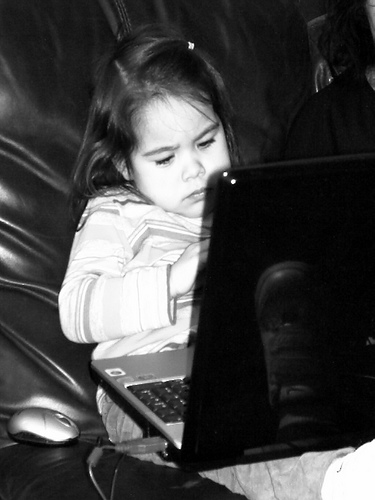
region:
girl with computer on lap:
[43, 40, 368, 487]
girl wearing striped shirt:
[45, 171, 303, 353]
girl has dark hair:
[66, 28, 263, 210]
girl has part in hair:
[83, 45, 162, 109]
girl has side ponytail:
[132, 32, 241, 100]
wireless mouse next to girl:
[0, 386, 100, 489]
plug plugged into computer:
[70, 416, 181, 499]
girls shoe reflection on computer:
[235, 238, 357, 457]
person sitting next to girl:
[264, 0, 371, 203]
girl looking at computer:
[87, 69, 302, 282]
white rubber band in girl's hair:
[187, 39, 195, 50]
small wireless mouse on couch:
[5, 405, 81, 445]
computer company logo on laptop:
[105, 365, 126, 378]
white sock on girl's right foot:
[320, 427, 373, 498]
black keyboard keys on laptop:
[121, 374, 184, 425]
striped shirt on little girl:
[53, 187, 195, 377]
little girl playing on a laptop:
[43, 28, 234, 358]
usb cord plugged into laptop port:
[85, 431, 169, 499]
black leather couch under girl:
[1, 1, 257, 498]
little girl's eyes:
[131, 118, 225, 174]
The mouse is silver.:
[6, 405, 79, 449]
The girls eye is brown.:
[151, 152, 177, 164]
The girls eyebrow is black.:
[143, 143, 179, 164]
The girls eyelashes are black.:
[143, 145, 178, 165]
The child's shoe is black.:
[253, 263, 325, 404]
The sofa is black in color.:
[13, 232, 52, 297]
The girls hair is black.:
[71, 22, 235, 215]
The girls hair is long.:
[74, 21, 244, 237]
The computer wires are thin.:
[84, 437, 123, 499]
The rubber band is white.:
[185, 40, 196, 49]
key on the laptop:
[167, 414, 180, 424]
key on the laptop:
[158, 407, 168, 414]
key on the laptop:
[147, 397, 157, 401]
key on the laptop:
[138, 391, 150, 399]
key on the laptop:
[130, 382, 154, 387]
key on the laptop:
[159, 385, 170, 394]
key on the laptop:
[167, 393, 177, 399]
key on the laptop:
[172, 397, 182, 406]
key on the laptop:
[175, 403, 183, 411]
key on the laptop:
[173, 378, 181, 384]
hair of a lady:
[165, 15, 201, 51]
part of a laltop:
[208, 409, 232, 443]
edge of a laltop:
[183, 377, 196, 402]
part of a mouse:
[32, 404, 70, 453]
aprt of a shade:
[281, 396, 301, 426]